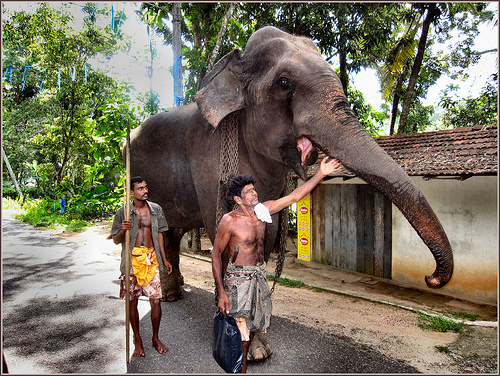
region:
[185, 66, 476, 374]
man touching an elephant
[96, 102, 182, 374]
man carrying a large stick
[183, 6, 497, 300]
an elephant with its mouth open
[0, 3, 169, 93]
blue flags hanging from trees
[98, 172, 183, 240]
man with dark hair & mustache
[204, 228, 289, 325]
knife handle at man's waist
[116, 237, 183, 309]
yellow fabric around man's waiste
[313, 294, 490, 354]
weeds growing in crack of cement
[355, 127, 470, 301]
an elephant's trunk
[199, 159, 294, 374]
man with a black bag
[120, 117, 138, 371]
man holding a long sharp pole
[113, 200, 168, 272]
man wearing an open short sleeve shirt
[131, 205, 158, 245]
chest visible under shirt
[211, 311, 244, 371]
black plastic bag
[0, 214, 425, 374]
elephant walking on paved road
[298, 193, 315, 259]
yellow sign on building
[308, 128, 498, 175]
shingled roof on building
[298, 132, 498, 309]
building to the right of elephant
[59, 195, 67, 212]
blue cloth in bush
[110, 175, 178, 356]
man is barefoot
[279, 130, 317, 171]
An open elephants mouth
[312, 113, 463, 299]
Elephants trunk extended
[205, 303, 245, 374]
Blue bag in a persons hand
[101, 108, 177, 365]
A person holding a long pole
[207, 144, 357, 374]
A person touching an elephants trunk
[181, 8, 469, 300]
Elephants head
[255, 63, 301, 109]
Elephants right eye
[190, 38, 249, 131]
Elephants right ear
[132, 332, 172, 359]
Bare feet on pavement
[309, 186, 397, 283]
Boards on the side of a building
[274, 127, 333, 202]
the elephant has it's mouth open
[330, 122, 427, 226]
the elephant has a long trunk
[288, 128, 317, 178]
the elephants tongue is pink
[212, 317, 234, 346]
the bag is blue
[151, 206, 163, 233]
the shirt is green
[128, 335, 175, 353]
the guy has no shoes on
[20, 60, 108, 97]
the string is light blue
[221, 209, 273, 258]
the guy is shirtless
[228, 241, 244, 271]
the knife handle is brown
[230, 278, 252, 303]
the shorts are gray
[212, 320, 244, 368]
bag in man's hand.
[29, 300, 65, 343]
shadow on the ground.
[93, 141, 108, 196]
leaves on the tree.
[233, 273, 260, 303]
shorts on man's waist.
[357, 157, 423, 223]
trunk of the elephant.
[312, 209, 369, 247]
wooden panels on building.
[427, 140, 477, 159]
roof of the building.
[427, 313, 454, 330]
weeds on the ground.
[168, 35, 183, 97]
trunk of the tree.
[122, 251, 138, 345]
staff in man's hand.